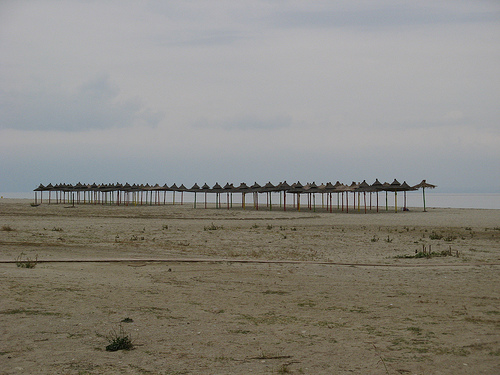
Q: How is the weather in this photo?
A: It is cloudy.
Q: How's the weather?
A: It is cloudy.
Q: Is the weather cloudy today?
A: Yes, it is cloudy.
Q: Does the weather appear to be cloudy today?
A: Yes, it is cloudy.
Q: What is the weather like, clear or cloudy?
A: It is cloudy.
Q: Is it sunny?
A: No, it is cloudy.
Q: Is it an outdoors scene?
A: Yes, it is outdoors.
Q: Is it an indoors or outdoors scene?
A: It is outdoors.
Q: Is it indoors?
A: No, it is outdoors.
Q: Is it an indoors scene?
A: No, it is outdoors.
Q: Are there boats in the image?
A: No, there are no boats.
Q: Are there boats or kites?
A: No, there are no boats or kites.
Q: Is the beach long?
A: Yes, the beach is long.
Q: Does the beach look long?
A: Yes, the beach is long.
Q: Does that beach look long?
A: Yes, the beach is long.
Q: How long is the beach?
A: The beach is long.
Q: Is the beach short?
A: No, the beach is long.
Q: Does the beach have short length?
A: No, the beach is long.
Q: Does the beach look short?
A: No, the beach is long.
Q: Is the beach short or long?
A: The beach is long.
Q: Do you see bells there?
A: No, there are no bells.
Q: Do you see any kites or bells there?
A: No, there are no bells or kites.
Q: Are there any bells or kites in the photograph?
A: No, there are no bells or kites.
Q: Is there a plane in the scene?
A: No, there are no airplanes.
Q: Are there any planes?
A: No, there are no planes.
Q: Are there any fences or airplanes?
A: No, there are no airplanes or fences.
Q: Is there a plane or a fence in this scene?
A: No, there are no airplanes or fences.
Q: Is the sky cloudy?
A: Yes, the sky is cloudy.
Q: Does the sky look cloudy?
A: Yes, the sky is cloudy.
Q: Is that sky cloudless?
A: No, the sky is cloudy.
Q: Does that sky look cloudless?
A: No, the sky is cloudy.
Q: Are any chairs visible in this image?
A: No, there are no chairs.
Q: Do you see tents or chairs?
A: No, there are no chairs or tents.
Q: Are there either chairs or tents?
A: No, there are no chairs or tents.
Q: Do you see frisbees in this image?
A: No, there are no frisbees.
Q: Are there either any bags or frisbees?
A: No, there are no frisbees or bags.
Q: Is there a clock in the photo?
A: No, there are no clocks.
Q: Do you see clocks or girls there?
A: No, there are no clocks or girls.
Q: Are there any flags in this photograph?
A: No, there are no flags.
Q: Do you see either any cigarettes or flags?
A: No, there are no flags or cigarettes.